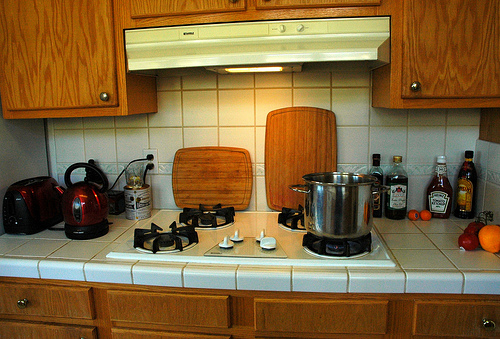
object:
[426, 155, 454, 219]
bottle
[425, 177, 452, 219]
ketchup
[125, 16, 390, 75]
hood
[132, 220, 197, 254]
stove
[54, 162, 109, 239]
kettle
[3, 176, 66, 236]
toaster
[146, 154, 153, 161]
plug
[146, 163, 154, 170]
plug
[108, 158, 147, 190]
wire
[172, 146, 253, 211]
board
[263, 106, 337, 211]
board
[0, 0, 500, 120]
cabinets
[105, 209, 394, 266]
surface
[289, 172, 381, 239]
pot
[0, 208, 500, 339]
counter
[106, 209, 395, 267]
burners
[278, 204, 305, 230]
stove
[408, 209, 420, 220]
tangerine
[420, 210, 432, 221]
tangerine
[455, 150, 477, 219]
bottle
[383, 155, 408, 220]
bottle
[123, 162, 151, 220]
appliances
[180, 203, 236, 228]
stove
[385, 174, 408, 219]
olive oil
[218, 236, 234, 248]
knob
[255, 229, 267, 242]
knob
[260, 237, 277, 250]
knob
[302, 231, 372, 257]
stove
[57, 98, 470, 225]
wall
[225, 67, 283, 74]
lights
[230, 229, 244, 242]
knob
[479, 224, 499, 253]
orange